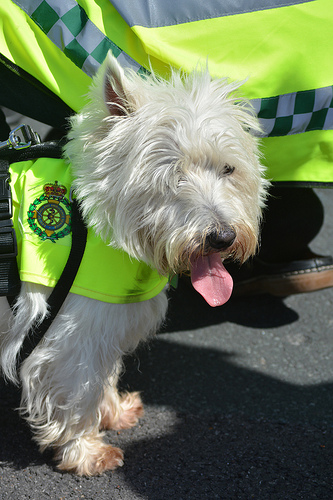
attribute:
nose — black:
[200, 222, 240, 254]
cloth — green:
[11, 139, 163, 309]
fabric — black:
[6, 71, 71, 130]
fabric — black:
[50, 13, 123, 62]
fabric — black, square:
[27, 0, 60, 31]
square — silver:
[77, 19, 107, 52]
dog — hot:
[6, 39, 274, 488]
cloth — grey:
[255, 88, 332, 136]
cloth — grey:
[251, 85, 332, 138]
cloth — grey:
[276, 94, 297, 115]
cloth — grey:
[54, 16, 104, 58]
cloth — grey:
[34, 9, 115, 56]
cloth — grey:
[54, 15, 113, 62]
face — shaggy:
[71, 48, 267, 270]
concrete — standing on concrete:
[210, 393, 280, 491]